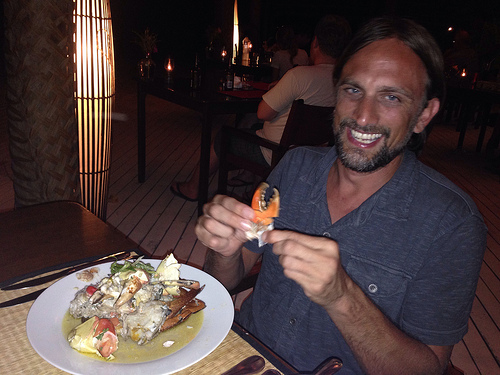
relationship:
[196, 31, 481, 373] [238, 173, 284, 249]
man eating seafood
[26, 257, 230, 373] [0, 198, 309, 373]
plate on table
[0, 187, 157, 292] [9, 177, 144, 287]
folder on table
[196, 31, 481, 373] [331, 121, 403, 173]
man has beard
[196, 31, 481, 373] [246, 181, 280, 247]
man holding claw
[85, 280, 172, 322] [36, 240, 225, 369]
seafood displayed on plate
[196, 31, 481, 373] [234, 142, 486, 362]
man wearing blue shirt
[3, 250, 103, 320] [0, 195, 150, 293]
utensil on table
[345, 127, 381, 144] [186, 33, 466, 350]
smile of man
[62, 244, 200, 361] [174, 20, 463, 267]
meal eaten by man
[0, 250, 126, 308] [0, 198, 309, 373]
utensils on table